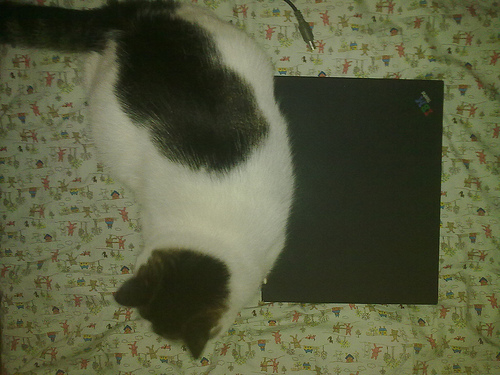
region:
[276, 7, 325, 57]
unplugged cord with silver tip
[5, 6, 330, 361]
white and black cat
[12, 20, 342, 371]
white cat with black spots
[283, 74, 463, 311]
black mouse pad with small logo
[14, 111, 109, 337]
orange and green floral sheets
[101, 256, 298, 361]
cat's head looking down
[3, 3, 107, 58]
black tail of a cat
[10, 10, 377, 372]
cat laying on floral bedsheets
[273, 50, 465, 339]
mouse pad laying on floral bed sheets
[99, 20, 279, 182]
glossy black spot on a cat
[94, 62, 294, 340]
The cat is black and white.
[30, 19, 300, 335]
The cat is sitting on the bed.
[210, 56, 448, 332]
A black laptop sits nest to the cat.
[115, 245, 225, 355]
the cat head is black.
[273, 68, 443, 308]
The laptop is black.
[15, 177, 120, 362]
the bedspread has objects on it.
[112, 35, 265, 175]
The cat has a big black spot on his back.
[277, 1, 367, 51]
The cord to the laptop.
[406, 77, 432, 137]
The laptop says IBM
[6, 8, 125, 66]
The cat tail is black.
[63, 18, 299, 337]
the cat is on the bed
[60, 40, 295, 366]
the cat is black and white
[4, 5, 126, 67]
the tail is black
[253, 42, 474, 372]
the laptop is on the bed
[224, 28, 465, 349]
the laptop is beside the cat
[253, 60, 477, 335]
the laptop is black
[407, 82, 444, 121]
the logo is IBM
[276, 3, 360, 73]
the cord is black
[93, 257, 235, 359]
cat's ears are brown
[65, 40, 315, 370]
the cat is sitting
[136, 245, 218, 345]
Cat has dark fur on head.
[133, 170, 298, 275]
Cat has white fur on back.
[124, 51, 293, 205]
Dark spot of fur near cat's rear end.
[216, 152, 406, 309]
Cat is laying near computer.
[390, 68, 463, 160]
Computer is black in color.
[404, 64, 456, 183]
Computer is IBM brand.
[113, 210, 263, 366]
Cat is laying on bed.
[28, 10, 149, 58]
Cat has dark fur on tail.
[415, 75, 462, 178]
IBM is in red green and blue.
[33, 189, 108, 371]
Lots of different little pictures on bed spread.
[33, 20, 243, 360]
Picture taken indoors.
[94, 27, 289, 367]
A cat's back from top.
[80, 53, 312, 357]
The cat has multiple colors.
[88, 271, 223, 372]
The cat has furry ears.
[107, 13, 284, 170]
The cat has a large spot on the back.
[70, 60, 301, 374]
The cat is laying down.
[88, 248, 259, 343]
You cannot see the cat's eyes.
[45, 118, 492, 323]
The cat is laying on top of a blanket.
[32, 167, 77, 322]
The blanket is floral in design.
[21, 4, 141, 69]
The cat has a furry tail.